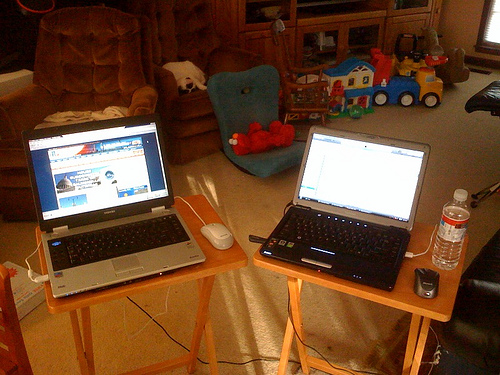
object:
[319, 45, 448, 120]
toy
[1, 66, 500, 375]
floor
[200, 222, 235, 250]
mouse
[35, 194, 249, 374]
computer desk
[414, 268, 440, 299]
mouse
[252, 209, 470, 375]
computer desk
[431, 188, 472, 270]
water bottle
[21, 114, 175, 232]
screen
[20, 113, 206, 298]
computer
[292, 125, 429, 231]
screen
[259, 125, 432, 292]
computer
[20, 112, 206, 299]
laptop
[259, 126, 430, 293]
laptop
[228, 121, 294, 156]
stuffed animal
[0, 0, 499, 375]
room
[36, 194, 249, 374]
stand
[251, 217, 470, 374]
stand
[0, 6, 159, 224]
reclining chair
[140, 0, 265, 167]
recliner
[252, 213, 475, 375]
tv table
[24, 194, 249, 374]
tv table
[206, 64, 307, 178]
game chair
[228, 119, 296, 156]
tickle me elmo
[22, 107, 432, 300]
laptops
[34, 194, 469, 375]
tables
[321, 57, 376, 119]
toy house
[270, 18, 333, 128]
rocking chair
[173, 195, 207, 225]
cord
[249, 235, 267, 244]
flash drive